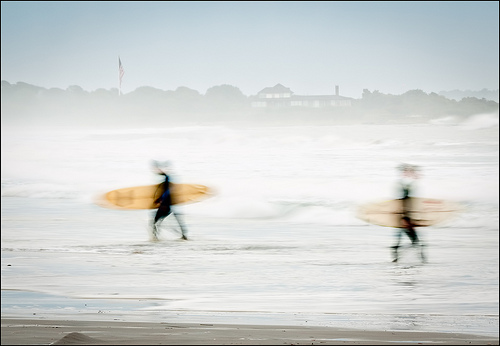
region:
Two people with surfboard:
[106, 153, 465, 266]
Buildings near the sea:
[263, 78, 353, 120]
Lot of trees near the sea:
[16, 81, 241, 102]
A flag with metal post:
[111, 56, 134, 98]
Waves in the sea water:
[433, 110, 496, 137]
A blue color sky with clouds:
[277, 20, 445, 59]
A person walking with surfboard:
[93, 152, 218, 248]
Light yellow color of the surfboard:
[103, 185, 144, 220]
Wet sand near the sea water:
[36, 321, 146, 344]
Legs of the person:
[149, 220, 205, 244]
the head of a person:
[158, 166, 175, 182]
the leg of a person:
[164, 205, 192, 242]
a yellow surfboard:
[94, 180, 215, 215]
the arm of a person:
[147, 176, 166, 207]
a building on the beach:
[246, 81, 365, 123]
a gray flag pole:
[111, 53, 130, 98]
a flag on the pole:
[113, 54, 126, 86]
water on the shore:
[0, 118, 497, 318]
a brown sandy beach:
[3, 315, 499, 344]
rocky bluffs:
[0, 78, 495, 128]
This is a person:
[89, 150, 229, 281]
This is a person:
[369, 153, 457, 299]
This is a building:
[254, 73, 294, 105]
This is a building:
[289, 90, 363, 118]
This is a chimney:
[332, 77, 346, 106]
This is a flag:
[112, 54, 127, 110]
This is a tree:
[61, 80, 90, 122]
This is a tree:
[127, 72, 174, 120]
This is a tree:
[206, 68, 245, 130]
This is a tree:
[16, 68, 67, 145]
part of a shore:
[266, 250, 306, 295]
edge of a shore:
[238, 276, 267, 326]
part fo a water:
[298, 248, 333, 296]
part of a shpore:
[273, 260, 311, 319]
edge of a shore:
[222, 286, 254, 332]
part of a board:
[180, 184, 205, 237]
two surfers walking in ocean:
[92, 138, 458, 258]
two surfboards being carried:
[88, 166, 453, 234]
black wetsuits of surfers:
[140, 180, 429, 268]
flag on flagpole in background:
[115, 52, 122, 95]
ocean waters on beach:
[17, 98, 489, 316]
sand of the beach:
[10, 245, 488, 342]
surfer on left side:
[97, 144, 202, 248]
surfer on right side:
[347, 145, 472, 257]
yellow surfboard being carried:
[80, 158, 218, 212]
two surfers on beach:
[101, 153, 457, 265]